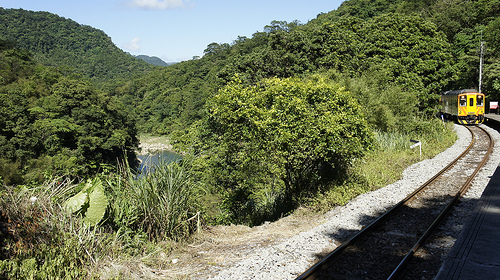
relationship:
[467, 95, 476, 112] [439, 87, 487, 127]
door near train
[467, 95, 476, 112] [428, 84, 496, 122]
door on train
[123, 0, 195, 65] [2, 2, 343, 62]
clouds in sky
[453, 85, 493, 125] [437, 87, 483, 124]
face on train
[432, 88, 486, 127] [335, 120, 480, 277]
train on track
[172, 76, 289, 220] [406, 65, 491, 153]
tree next to train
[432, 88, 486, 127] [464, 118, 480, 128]
train has bottom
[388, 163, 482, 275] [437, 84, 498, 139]
track with train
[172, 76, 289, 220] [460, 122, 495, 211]
tree along track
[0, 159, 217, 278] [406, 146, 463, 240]
bush along track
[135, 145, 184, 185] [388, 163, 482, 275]
river along track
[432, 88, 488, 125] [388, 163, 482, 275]
train traveling on track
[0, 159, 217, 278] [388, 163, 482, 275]
bush beside track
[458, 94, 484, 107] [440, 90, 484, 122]
windows on train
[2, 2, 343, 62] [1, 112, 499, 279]
sky above land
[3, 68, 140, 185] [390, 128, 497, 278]
bush along track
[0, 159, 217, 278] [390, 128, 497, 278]
bush along track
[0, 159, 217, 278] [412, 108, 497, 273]
bush along track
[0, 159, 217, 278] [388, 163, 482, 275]
bush along track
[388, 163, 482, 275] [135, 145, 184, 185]
track along river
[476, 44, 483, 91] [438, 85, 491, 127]
pole next to train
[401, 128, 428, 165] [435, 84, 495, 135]
traffic marker of train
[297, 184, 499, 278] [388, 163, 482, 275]
shadow on track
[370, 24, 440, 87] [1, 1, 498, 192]
leaves on trees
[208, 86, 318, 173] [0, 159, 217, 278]
leaf in bush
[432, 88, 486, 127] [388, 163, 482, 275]
train on track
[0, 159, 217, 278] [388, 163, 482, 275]
bush on track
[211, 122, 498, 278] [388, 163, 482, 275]
gravel on track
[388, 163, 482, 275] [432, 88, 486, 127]
track under train